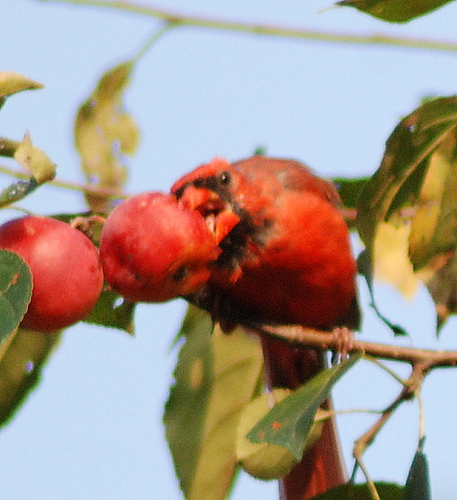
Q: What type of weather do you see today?
A: It is clear.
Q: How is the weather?
A: It is clear.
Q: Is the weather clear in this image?
A: Yes, it is clear.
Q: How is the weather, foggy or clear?
A: It is clear.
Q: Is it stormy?
A: No, it is clear.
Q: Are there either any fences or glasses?
A: No, there are no fences or glasses.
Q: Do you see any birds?
A: Yes, there is a bird.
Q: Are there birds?
A: Yes, there is a bird.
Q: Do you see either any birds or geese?
A: Yes, there is a bird.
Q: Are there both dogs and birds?
A: No, there is a bird but no dogs.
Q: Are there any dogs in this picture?
A: No, there are no dogs.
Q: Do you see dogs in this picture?
A: No, there are no dogs.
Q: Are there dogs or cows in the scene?
A: No, there are no dogs or cows.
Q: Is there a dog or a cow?
A: No, there are no dogs or cows.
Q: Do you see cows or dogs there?
A: No, there are no dogs or cows.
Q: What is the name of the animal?
A: The animal is a bird.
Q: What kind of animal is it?
A: The animal is a bird.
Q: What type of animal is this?
A: This is a bird.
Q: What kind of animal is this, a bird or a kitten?
A: This is a bird.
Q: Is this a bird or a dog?
A: This is a bird.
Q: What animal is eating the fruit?
A: The bird is eating the fruit.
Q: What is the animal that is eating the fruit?
A: The animal is a bird.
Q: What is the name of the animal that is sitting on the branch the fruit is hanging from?
A: The animal is a bird.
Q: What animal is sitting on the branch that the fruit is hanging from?
A: The animal is a bird.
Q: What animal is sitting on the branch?
A: The animal is a bird.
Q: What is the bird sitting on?
A: The bird is sitting on the branch.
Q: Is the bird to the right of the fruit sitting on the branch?
A: Yes, the bird is sitting on the branch.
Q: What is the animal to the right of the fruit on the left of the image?
A: The animal is a bird.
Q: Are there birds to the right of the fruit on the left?
A: Yes, there is a bird to the right of the fruit.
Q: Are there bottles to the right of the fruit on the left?
A: No, there is a bird to the right of the fruit.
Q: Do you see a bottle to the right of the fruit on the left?
A: No, there is a bird to the right of the fruit.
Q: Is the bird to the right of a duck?
A: No, the bird is to the right of the fruit.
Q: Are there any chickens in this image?
A: No, there are no chickens.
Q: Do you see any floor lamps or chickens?
A: No, there are no chickens or floor lamps.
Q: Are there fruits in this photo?
A: Yes, there is a fruit.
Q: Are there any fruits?
A: Yes, there is a fruit.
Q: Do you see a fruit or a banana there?
A: Yes, there is a fruit.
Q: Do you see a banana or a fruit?
A: Yes, there is a fruit.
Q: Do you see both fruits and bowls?
A: No, there is a fruit but no bowls.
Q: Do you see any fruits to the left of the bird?
A: Yes, there is a fruit to the left of the bird.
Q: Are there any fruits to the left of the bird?
A: Yes, there is a fruit to the left of the bird.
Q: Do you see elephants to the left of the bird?
A: No, there is a fruit to the left of the bird.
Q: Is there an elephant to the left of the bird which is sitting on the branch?
A: No, there is a fruit to the left of the bird.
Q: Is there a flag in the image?
A: No, there are no flags.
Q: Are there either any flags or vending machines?
A: No, there are no flags or vending machines.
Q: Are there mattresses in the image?
A: No, there are no mattresses.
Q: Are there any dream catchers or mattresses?
A: No, there are no mattresses or dream catchers.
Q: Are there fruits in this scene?
A: Yes, there is a fruit.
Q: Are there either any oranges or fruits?
A: Yes, there is a fruit.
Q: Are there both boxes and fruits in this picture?
A: No, there is a fruit but no boxes.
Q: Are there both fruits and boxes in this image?
A: No, there is a fruit but no boxes.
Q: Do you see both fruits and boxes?
A: No, there is a fruit but no boxes.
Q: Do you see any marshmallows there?
A: No, there are no marshmallows.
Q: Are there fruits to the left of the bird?
A: Yes, there is a fruit to the left of the bird.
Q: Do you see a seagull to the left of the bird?
A: No, there is a fruit to the left of the bird.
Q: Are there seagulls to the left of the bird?
A: No, there is a fruit to the left of the bird.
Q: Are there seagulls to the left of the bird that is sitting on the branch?
A: No, there is a fruit to the left of the bird.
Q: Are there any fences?
A: No, there are no fences.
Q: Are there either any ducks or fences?
A: No, there are no fences or ducks.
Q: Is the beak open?
A: Yes, the beak is open.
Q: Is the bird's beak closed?
A: No, the beak is open.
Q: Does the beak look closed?
A: No, the beak is open.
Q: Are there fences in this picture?
A: No, there are no fences.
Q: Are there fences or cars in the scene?
A: No, there are no fences or cars.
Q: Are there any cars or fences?
A: No, there are no fences or cars.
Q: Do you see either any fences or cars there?
A: No, there are no fences or cars.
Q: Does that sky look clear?
A: Yes, the sky is clear.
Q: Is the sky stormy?
A: No, the sky is clear.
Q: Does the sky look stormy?
A: No, the sky is clear.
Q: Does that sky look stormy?
A: No, the sky is clear.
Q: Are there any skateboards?
A: No, there are no skateboards.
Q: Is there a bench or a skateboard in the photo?
A: No, there are no skateboards or benches.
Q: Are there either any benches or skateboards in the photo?
A: No, there are no skateboards or benches.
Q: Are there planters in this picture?
A: No, there are no planters.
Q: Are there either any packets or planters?
A: No, there are no planters or packets.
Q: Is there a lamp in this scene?
A: No, there are no lamps.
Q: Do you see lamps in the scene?
A: No, there are no lamps.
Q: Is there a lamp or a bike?
A: No, there are no lamps or bikes.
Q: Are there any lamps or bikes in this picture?
A: No, there are no lamps or bikes.